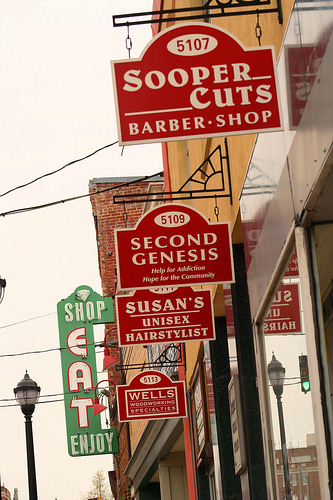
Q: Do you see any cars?
A: No, there are no cars.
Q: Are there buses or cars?
A: No, there are no cars or buses.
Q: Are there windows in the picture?
A: Yes, there is a window.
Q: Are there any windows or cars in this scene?
A: Yes, there is a window.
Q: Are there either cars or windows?
A: Yes, there is a window.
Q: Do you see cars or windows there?
A: Yes, there is a window.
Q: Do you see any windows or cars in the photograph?
A: Yes, there is a window.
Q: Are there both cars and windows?
A: No, there is a window but no cars.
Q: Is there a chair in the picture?
A: No, there are no chairs.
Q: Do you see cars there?
A: No, there are no cars.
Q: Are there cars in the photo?
A: No, there are no cars.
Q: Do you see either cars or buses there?
A: No, there are no cars or buses.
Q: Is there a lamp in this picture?
A: Yes, there is a lamp.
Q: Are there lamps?
A: Yes, there is a lamp.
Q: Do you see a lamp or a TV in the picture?
A: Yes, there is a lamp.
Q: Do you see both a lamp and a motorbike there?
A: No, there is a lamp but no motorcycles.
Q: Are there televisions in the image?
A: No, there are no televisions.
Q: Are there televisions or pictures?
A: No, there are no televisions or pictures.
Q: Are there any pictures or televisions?
A: No, there are no televisions or pictures.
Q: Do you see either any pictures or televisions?
A: No, there are no televisions or pictures.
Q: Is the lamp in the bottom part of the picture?
A: Yes, the lamp is in the bottom of the image.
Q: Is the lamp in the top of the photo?
A: No, the lamp is in the bottom of the image.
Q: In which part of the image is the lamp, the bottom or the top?
A: The lamp is in the bottom of the image.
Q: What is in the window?
A: The lamp is in the window.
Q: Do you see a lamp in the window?
A: Yes, there is a lamp in the window.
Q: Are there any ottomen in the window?
A: No, there is a lamp in the window.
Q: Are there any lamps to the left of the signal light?
A: Yes, there is a lamp to the left of the signal light.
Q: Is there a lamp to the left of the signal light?
A: Yes, there is a lamp to the left of the signal light.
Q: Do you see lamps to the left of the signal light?
A: Yes, there is a lamp to the left of the signal light.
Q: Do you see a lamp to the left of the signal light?
A: Yes, there is a lamp to the left of the signal light.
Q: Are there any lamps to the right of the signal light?
A: No, the lamp is to the left of the signal light.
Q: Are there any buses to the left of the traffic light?
A: No, there is a lamp to the left of the traffic light.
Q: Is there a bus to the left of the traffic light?
A: No, there is a lamp to the left of the traffic light.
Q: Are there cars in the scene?
A: No, there are no cars.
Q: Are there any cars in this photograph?
A: No, there are no cars.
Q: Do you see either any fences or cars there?
A: No, there are no cars or fences.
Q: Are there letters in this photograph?
A: Yes, there are letters.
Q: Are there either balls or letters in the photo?
A: Yes, there are letters.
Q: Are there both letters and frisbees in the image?
A: No, there are letters but no frisbees.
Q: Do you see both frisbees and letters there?
A: No, there are letters but no frisbees.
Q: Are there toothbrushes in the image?
A: No, there are no toothbrushes.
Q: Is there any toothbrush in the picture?
A: No, there are no toothbrushes.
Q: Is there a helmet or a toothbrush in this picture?
A: No, there are no toothbrushes or helmets.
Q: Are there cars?
A: No, there are no cars.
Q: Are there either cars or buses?
A: No, there are no cars or buses.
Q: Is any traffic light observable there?
A: Yes, there is a traffic light.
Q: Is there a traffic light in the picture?
A: Yes, there is a traffic light.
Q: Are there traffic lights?
A: Yes, there is a traffic light.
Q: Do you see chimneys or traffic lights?
A: Yes, there is a traffic light.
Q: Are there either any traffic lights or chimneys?
A: Yes, there is a traffic light.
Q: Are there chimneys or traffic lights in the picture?
A: Yes, there is a traffic light.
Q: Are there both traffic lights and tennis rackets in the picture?
A: No, there is a traffic light but no rackets.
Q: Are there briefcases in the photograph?
A: No, there are no briefcases.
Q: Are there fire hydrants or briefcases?
A: No, there are no briefcases or fire hydrants.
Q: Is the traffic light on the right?
A: Yes, the traffic light is on the right of the image.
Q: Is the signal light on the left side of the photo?
A: No, the signal light is on the right of the image.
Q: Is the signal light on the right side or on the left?
A: The signal light is on the right of the image.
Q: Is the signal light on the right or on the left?
A: The signal light is on the right of the image.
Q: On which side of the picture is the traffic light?
A: The traffic light is on the right of the image.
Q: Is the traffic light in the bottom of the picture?
A: Yes, the traffic light is in the bottom of the image.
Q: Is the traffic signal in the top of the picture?
A: No, the traffic signal is in the bottom of the image.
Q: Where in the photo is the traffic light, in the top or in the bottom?
A: The traffic light is in the bottom of the image.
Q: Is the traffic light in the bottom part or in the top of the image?
A: The traffic light is in the bottom of the image.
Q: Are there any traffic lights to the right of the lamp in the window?
A: Yes, there is a traffic light to the right of the lamp.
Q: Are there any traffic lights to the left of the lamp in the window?
A: No, the traffic light is to the right of the lamp.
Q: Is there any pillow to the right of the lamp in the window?
A: No, there is a traffic light to the right of the lamp.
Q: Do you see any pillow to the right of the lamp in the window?
A: No, there is a traffic light to the right of the lamp.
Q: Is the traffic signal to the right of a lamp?
A: Yes, the traffic signal is to the right of a lamp.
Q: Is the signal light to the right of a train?
A: No, the signal light is to the right of a lamp.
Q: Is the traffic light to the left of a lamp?
A: No, the traffic light is to the right of a lamp.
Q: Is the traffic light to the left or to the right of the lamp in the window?
A: The traffic light is to the right of the lamp.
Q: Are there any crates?
A: No, there are no crates.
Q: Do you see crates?
A: No, there are no crates.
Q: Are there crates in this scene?
A: No, there are no crates.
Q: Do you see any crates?
A: No, there are no crates.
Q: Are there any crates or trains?
A: No, there are no crates or trains.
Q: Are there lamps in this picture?
A: Yes, there is a lamp.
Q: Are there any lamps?
A: Yes, there is a lamp.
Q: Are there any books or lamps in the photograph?
A: Yes, there is a lamp.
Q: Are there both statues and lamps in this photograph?
A: No, there is a lamp but no statues.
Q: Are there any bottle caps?
A: No, there are no bottle caps.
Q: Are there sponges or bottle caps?
A: No, there are no bottle caps or sponges.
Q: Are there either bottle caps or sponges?
A: No, there are no bottle caps or sponges.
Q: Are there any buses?
A: No, there are no buses.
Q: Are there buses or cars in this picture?
A: No, there are no buses or cars.